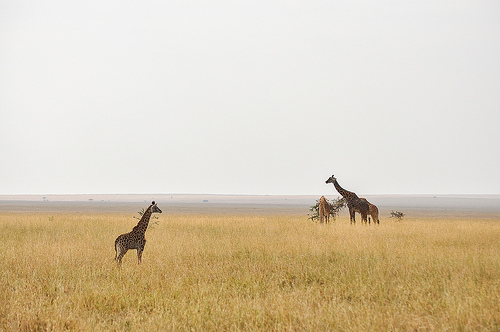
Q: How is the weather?
A: It is clear.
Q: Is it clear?
A: Yes, it is clear.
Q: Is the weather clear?
A: Yes, it is clear.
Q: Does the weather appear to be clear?
A: Yes, it is clear.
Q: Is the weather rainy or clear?
A: It is clear.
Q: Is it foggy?
A: No, it is clear.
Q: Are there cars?
A: No, there are no cars.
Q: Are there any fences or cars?
A: No, there are no cars or fences.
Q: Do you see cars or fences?
A: No, there are no cars or fences.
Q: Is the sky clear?
A: Yes, the sky is clear.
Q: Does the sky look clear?
A: Yes, the sky is clear.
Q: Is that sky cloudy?
A: No, the sky is clear.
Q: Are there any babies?
A: Yes, there is a baby.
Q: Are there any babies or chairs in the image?
A: Yes, there is a baby.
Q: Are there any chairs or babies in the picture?
A: Yes, there is a baby.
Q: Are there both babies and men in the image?
A: No, there is a baby but no men.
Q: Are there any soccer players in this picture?
A: No, there are no soccer players.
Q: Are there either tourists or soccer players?
A: No, there are no soccer players or tourists.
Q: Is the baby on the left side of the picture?
A: Yes, the baby is on the left of the image.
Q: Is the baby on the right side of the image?
A: No, the baby is on the left of the image.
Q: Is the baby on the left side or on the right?
A: The baby is on the left of the image.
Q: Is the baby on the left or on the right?
A: The baby is on the left of the image.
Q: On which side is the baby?
A: The baby is on the left of the image.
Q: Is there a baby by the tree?
A: Yes, there is a baby by the tree.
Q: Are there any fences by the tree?
A: No, there is a baby by the tree.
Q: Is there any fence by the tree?
A: No, there is a baby by the tree.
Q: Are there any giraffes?
A: Yes, there is a giraffe.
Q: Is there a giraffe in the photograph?
A: Yes, there is a giraffe.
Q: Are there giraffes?
A: Yes, there is a giraffe.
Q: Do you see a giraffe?
A: Yes, there is a giraffe.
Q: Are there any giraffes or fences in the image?
A: Yes, there is a giraffe.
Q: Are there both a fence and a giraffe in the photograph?
A: No, there is a giraffe but no fences.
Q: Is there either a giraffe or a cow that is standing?
A: Yes, the giraffe is standing.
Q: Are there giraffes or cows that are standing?
A: Yes, the giraffe is standing.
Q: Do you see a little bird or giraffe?
A: Yes, there is a little giraffe.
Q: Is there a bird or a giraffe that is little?
A: Yes, the giraffe is little.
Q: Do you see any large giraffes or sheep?
A: Yes, there is a large giraffe.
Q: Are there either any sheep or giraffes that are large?
A: Yes, the giraffe is large.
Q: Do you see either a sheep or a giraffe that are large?
A: Yes, the giraffe is large.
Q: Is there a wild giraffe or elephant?
A: Yes, there is a wild giraffe.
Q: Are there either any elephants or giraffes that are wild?
A: Yes, the giraffe is wild.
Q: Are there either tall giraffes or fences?
A: Yes, there is a tall giraffe.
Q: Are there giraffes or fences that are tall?
A: Yes, the giraffe is tall.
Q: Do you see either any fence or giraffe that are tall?
A: Yes, the giraffe is tall.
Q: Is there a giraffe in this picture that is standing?
A: Yes, there is a giraffe that is standing.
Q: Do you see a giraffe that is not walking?
A: Yes, there is a giraffe that is standing .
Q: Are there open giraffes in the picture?
A: Yes, there is an open giraffe.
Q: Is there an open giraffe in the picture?
A: Yes, there is an open giraffe.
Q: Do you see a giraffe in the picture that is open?
A: Yes, there is a giraffe that is open.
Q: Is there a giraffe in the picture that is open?
A: Yes, there is a giraffe that is open.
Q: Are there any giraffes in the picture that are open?
A: Yes, there is a giraffe that is open.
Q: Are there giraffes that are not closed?
A: Yes, there is a open giraffe.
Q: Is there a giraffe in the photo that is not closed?
A: Yes, there is a open giraffe.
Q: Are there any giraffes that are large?
A: Yes, there is a large giraffe.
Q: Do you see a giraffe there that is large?
A: Yes, there is a giraffe that is large.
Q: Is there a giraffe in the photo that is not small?
A: Yes, there is a large giraffe.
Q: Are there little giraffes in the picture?
A: Yes, there is a little giraffe.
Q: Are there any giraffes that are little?
A: Yes, there is a giraffe that is little.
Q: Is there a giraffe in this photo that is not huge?
A: Yes, there is a little giraffe.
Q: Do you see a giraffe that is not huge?
A: Yes, there is a little giraffe.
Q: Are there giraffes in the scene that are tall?
A: Yes, there is a tall giraffe.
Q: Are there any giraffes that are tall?
A: Yes, there is a giraffe that is tall.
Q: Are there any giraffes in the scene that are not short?
A: Yes, there is a tall giraffe.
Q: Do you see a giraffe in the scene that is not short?
A: Yes, there is a tall giraffe.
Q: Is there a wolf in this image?
A: No, there are no wolves.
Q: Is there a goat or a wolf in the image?
A: No, there are no wolves or goats.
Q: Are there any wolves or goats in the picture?
A: No, there are no wolves or goats.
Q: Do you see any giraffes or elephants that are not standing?
A: No, there is a giraffe but it is standing.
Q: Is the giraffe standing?
A: Yes, the giraffe is standing.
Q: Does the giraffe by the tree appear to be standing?
A: Yes, the giraffe is standing.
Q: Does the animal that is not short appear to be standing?
A: Yes, the giraffe is standing.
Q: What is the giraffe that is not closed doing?
A: The giraffe is standing.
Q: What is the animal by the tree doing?
A: The giraffe is standing.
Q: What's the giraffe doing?
A: The giraffe is standing.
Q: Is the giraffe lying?
A: No, the giraffe is standing.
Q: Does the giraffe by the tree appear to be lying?
A: No, the giraffe is standing.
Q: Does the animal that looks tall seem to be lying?
A: No, the giraffe is standing.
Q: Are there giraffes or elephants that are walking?
A: No, there is a giraffe but it is standing.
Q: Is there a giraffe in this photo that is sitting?
A: No, there is a giraffe but it is standing.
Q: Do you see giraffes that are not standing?
A: No, there is a giraffe but it is standing.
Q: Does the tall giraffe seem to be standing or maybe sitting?
A: The giraffe is standing.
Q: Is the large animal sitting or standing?
A: The giraffe is standing.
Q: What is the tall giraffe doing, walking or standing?
A: The giraffe is standing.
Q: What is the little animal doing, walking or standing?
A: The giraffe is standing.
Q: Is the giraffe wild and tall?
A: Yes, the giraffe is wild and tall.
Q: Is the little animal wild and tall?
A: Yes, the giraffe is wild and tall.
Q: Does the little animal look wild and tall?
A: Yes, the giraffe is wild and tall.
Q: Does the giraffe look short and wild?
A: No, the giraffe is wild but tall.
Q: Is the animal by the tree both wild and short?
A: No, the giraffe is wild but tall.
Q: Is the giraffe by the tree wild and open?
A: Yes, the giraffe is wild and open.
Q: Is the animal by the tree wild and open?
A: Yes, the giraffe is wild and open.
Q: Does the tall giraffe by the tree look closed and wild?
A: No, the giraffe is wild but open.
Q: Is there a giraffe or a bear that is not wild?
A: No, there is a giraffe but it is wild.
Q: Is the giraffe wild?
A: Yes, the giraffe is wild.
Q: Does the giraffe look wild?
A: Yes, the giraffe is wild.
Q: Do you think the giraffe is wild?
A: Yes, the giraffe is wild.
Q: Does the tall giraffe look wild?
A: Yes, the giraffe is wild.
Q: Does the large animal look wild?
A: Yes, the giraffe is wild.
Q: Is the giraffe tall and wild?
A: Yes, the giraffe is tall and wild.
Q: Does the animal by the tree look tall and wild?
A: Yes, the giraffe is tall and wild.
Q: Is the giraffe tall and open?
A: Yes, the giraffe is tall and open.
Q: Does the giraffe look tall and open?
A: Yes, the giraffe is tall and open.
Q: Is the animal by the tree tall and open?
A: Yes, the giraffe is tall and open.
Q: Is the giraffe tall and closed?
A: No, the giraffe is tall but open.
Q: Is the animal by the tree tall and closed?
A: No, the giraffe is tall but open.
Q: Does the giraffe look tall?
A: Yes, the giraffe is tall.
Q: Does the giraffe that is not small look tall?
A: Yes, the giraffe is tall.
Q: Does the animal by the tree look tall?
A: Yes, the giraffe is tall.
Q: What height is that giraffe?
A: The giraffe is tall.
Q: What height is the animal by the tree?
A: The giraffe is tall.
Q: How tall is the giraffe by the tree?
A: The giraffe is tall.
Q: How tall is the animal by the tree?
A: The giraffe is tall.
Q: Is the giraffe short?
A: No, the giraffe is tall.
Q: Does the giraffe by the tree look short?
A: No, the giraffe is tall.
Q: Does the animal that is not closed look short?
A: No, the giraffe is tall.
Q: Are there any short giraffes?
A: No, there is a giraffe but it is tall.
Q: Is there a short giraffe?
A: No, there is a giraffe but it is tall.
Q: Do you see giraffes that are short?
A: No, there is a giraffe but it is tall.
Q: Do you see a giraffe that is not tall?
A: No, there is a giraffe but it is tall.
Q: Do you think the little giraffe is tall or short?
A: The giraffe is tall.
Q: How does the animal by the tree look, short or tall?
A: The giraffe is tall.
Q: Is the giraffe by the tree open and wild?
A: Yes, the giraffe is open and wild.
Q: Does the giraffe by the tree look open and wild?
A: Yes, the giraffe is open and wild.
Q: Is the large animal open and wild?
A: Yes, the giraffe is open and wild.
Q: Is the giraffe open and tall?
A: Yes, the giraffe is open and tall.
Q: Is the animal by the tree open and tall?
A: Yes, the giraffe is open and tall.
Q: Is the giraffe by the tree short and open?
A: No, the giraffe is open but tall.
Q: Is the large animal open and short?
A: No, the giraffe is open but tall.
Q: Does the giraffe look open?
A: Yes, the giraffe is open.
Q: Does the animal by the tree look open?
A: Yes, the giraffe is open.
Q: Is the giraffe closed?
A: No, the giraffe is open.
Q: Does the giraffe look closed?
A: No, the giraffe is open.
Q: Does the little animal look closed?
A: No, the giraffe is open.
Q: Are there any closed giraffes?
A: No, there is a giraffe but it is open.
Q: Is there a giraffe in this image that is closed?
A: No, there is a giraffe but it is open.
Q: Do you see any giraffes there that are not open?
A: No, there is a giraffe but it is open.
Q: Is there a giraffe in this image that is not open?
A: No, there is a giraffe but it is open.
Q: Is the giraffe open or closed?
A: The giraffe is open.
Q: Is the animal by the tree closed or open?
A: The giraffe is open.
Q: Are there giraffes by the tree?
A: Yes, there is a giraffe by the tree.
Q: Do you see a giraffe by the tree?
A: Yes, there is a giraffe by the tree.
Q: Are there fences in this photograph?
A: No, there are no fences.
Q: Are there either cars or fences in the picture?
A: No, there are no fences or cars.